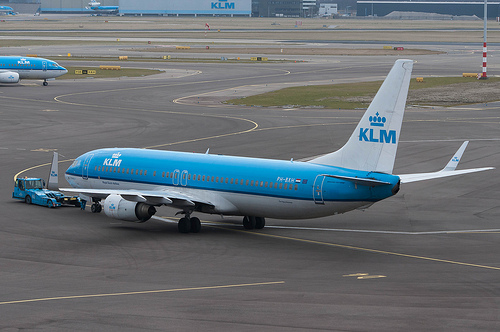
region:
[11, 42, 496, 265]
a commercial jet being pulled by a truck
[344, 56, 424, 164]
the tail-fin of a jet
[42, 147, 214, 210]
the wing of a jet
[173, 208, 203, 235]
the landing gear of a jet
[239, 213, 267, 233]
the landing gear of a jet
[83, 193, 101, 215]
the nose-wheel of a jet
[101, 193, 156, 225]
the engine of a jet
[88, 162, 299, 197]
the passenger windows of a jet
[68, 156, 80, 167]
the cockpit of a jet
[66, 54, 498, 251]
a KLM commercial jet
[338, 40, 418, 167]
the tail-fin of a jet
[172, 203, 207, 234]
the landing gear of a jet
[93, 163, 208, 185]
the passenger windows of a jet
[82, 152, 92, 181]
the passenger loading door of a jet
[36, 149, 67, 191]
the winglet on a jet wing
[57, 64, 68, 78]
the nosecone of a jet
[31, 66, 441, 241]
a big blue and white airplane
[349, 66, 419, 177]
the tail of an airplane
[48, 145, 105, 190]
the nose of an airplane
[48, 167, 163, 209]
the wing of an airplane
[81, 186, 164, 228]
the turbine of an airplane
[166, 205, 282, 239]
the wheel of an airplane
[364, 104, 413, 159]
the logo of an airplane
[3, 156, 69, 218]
the cart that transports luggage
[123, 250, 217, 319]
the airports runway that the airplane goes down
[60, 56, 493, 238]
blue and white plane on a tarmac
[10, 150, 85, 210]
blue truck in front of the plane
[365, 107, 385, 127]
blue logo on tail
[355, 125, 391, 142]
blue letters on the tail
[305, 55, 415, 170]
white tail of plane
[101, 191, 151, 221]
engine on the plane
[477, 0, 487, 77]
pole with red and white stripes on it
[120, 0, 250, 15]
white sign in background with blue letters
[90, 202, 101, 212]
front landing wheels on the plane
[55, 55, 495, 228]
Blue and white plane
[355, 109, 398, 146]
Blue logo on white tail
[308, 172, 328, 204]
Blue door by white tail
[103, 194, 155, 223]
Large jet engine under wing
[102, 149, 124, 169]
White logo on blue plane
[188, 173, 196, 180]
Small window next to wing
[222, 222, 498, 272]
Yellow line under plane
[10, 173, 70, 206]
Blue car in front of plane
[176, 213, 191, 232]
Black tire under plane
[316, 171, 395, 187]
Large horizontal stabilizer by tail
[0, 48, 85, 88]
a blue and white plane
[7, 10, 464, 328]
a large runway area for a plane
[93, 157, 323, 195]
windows on a plate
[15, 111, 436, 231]
a large blue plane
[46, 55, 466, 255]
a large blue plane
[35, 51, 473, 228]
a large blue plane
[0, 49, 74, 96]
a large blue plane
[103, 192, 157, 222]
engine belongs to plane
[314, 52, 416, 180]
taillight belongs to plane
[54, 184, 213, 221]
wing belongs to plane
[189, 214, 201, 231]
wheel belongs to plane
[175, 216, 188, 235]
wheel belongs to plane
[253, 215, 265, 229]
wheel belongs to plane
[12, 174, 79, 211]
vehicle in front of plane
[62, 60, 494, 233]
plane behind vehicle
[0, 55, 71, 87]
plane is blue and white